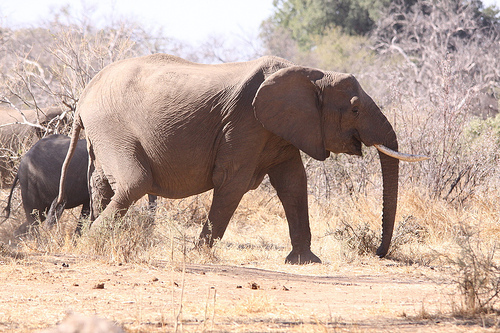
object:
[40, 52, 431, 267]
elephant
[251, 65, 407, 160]
head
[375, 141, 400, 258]
trunk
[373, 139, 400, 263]
tusk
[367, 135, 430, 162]
tusk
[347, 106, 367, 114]
eye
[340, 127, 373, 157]
mouth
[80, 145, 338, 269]
legs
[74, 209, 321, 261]
feet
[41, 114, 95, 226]
tail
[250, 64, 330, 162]
ear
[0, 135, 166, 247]
animal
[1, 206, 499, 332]
ground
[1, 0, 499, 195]
trees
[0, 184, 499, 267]
grass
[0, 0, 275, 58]
sky